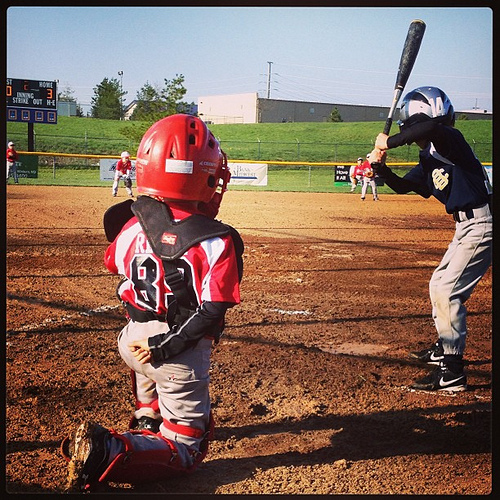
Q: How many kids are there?
A: 6.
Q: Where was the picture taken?
A: On the baseball field.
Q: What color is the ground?
A: Brown.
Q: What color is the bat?
A: Gray and black.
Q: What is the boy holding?
A: A bat.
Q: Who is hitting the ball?
A: The boy in black.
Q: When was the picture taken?
A: In the daytime.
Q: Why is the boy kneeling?
A: To catch the ball.